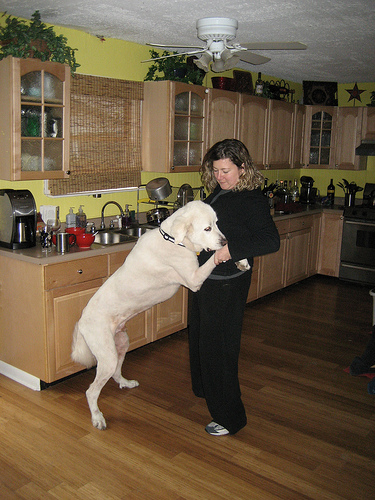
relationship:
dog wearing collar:
[73, 204, 222, 425] [156, 225, 179, 250]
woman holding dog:
[198, 138, 271, 430] [73, 204, 222, 425]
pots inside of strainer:
[153, 175, 171, 196] [140, 196, 169, 220]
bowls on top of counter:
[73, 229, 98, 250] [15, 245, 73, 272]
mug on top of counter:
[62, 215, 120, 243] [15, 245, 73, 272]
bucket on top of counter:
[175, 188, 190, 204] [15, 245, 73, 272]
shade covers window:
[88, 93, 143, 180] [57, 62, 139, 187]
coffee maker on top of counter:
[14, 213, 71, 252] [15, 245, 73, 272]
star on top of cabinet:
[321, 75, 366, 101] [4, 57, 64, 174]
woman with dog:
[198, 138, 271, 430] [73, 204, 222, 425]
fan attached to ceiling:
[172, 12, 302, 72] [323, 11, 353, 31]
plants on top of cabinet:
[1, 16, 69, 64] [4, 57, 64, 174]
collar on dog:
[156, 225, 179, 250] [73, 204, 222, 425]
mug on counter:
[62, 215, 120, 243] [15, 245, 73, 272]